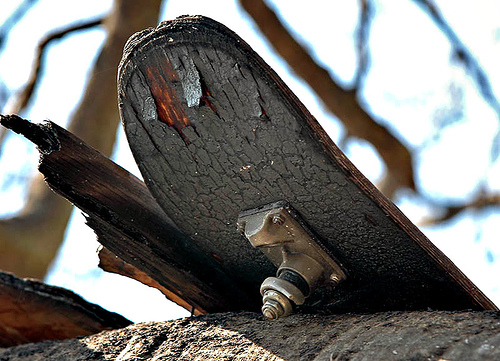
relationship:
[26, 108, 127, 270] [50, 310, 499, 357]
bark on log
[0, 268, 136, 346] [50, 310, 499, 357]
bark on log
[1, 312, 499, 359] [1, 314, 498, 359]
bark on log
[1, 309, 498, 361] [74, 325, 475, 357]
bark on log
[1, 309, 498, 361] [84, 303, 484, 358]
bark on log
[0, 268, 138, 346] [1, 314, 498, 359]
bark on log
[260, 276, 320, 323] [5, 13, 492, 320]
screw on board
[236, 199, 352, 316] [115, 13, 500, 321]
metal part on board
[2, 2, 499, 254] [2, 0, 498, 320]
tree branches are against sky